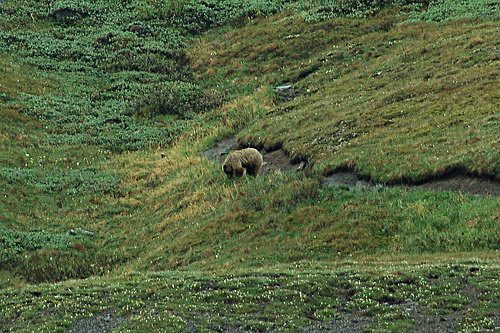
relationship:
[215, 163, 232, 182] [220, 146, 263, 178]
head head of bear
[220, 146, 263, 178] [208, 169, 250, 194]
bear sniffing grass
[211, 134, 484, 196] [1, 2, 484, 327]
trail through grass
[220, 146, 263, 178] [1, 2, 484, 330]
bear in field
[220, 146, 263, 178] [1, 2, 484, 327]
bear on grass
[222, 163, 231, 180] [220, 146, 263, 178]
head on bear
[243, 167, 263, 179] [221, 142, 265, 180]
leg on bear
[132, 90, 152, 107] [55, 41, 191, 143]
green leafy bushes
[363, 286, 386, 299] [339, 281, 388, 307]
white flower in grass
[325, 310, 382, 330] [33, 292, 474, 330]
gravel on ground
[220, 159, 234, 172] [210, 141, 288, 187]
ear of a bear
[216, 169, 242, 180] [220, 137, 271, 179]
snout of a bear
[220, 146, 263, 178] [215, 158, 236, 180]
bear has its head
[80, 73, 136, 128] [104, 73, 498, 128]
grass filled with shrubs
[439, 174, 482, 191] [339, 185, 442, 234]
dirt path in grass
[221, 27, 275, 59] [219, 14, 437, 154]
brown spots are in grass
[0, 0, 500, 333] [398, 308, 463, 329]
grass has rocks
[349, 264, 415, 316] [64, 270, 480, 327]
small flowers are growing in grass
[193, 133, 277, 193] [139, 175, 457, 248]
bear standing on ground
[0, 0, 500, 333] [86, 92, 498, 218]
grass on ground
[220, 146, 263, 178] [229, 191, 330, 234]
bear eating grass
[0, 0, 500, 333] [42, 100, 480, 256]
grass on ground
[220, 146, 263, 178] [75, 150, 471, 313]
bear eating below a hill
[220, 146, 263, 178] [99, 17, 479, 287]
bear in field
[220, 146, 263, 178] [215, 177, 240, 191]
bear looks food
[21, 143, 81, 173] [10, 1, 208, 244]
clover in field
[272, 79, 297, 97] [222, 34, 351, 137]
something on grass